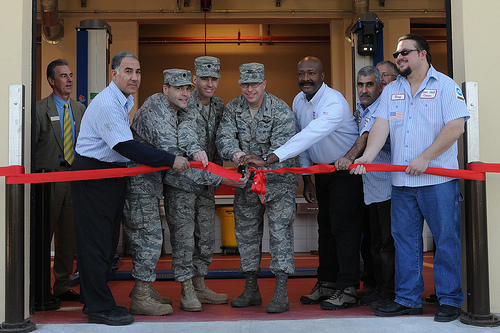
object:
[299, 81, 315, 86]
mustache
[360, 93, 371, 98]
mustache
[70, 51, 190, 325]
civilian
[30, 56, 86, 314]
civilian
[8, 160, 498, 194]
ribbon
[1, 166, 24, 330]
post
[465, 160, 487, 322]
post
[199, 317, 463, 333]
ground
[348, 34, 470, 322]
employess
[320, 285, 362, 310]
shoes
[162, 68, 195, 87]
hats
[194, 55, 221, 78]
hats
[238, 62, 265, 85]
hats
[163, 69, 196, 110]
heads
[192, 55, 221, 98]
heads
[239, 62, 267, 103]
heads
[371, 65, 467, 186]
blue shirt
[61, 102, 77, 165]
tie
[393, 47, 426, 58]
sunglasses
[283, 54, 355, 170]
man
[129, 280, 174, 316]
boots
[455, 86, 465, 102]
patch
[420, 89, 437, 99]
patch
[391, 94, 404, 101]
patch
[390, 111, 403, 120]
patch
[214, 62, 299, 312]
man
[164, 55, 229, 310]
man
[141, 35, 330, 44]
pipe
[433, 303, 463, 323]
shoe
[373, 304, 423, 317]
shoe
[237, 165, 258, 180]
scissors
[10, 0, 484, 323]
store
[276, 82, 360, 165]
shirt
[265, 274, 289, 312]
boots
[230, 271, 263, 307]
boots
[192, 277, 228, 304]
boots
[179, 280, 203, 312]
boots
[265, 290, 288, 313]
feet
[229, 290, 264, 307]
feet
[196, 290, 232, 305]
feet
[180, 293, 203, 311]
feet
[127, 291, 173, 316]
feet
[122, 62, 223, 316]
men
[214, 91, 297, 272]
uniform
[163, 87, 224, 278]
uniform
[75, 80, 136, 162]
blue shirt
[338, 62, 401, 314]
guys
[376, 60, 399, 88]
guys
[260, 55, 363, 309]
guys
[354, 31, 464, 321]
they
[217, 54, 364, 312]
they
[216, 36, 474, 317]
they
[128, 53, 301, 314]
they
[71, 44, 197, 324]
they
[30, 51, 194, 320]
they